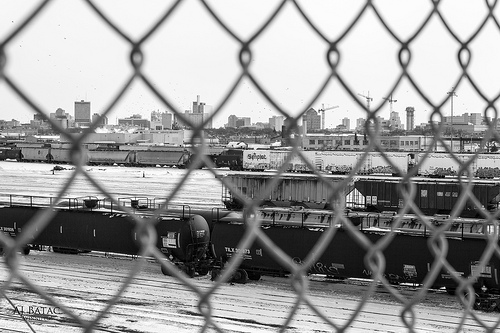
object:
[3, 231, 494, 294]
tracks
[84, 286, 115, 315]
snow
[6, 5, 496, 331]
fence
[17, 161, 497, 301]
cars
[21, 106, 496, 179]
building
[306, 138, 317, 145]
windows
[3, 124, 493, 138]
distance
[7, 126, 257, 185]
cars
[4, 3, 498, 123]
sky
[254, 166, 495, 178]
graffiti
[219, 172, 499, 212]
train